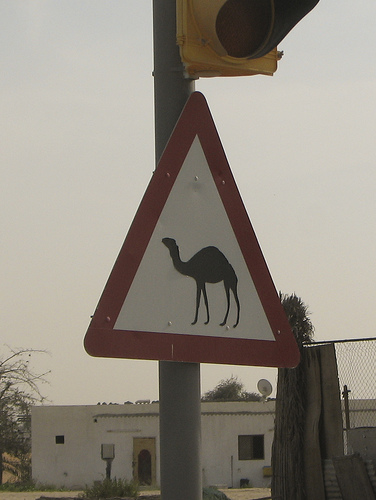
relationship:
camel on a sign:
[161, 235, 242, 329] [82, 89, 304, 372]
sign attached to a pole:
[82, 89, 304, 372] [147, 2, 206, 500]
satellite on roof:
[257, 377, 274, 401] [31, 397, 374, 413]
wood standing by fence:
[275, 339, 375, 500] [272, 338, 375, 500]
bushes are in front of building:
[79, 475, 141, 500] [29, 397, 374, 490]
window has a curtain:
[236, 434, 267, 464] [237, 435, 253, 460]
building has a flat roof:
[29, 397, 374, 490] [31, 397, 374, 413]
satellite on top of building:
[257, 377, 274, 401] [29, 397, 374, 490]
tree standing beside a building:
[3, 346, 56, 494] [29, 397, 374, 490]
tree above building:
[275, 288, 312, 353] [29, 397, 374, 490]